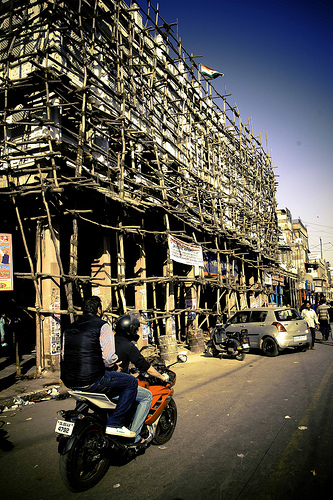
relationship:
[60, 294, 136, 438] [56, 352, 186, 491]
guy on bike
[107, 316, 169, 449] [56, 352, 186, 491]
guy on bike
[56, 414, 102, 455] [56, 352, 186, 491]
rear fender of a bike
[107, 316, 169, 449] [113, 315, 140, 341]
guy with helmet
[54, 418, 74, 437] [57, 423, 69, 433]
license plate with lettering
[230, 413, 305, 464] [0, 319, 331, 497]
debris in street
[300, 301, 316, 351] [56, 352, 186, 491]
man facing bike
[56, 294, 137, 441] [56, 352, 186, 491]
guy on bike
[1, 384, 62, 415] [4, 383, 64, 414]
curb littered with trash